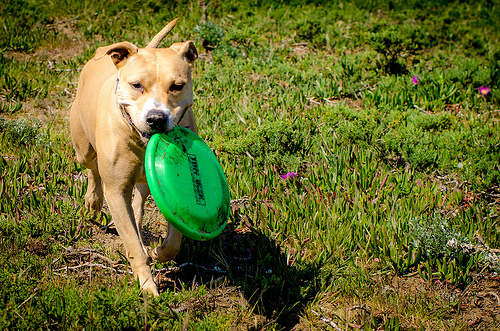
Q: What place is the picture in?
A: It is at the field.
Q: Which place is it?
A: It is a field.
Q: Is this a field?
A: Yes, it is a field.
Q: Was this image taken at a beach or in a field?
A: It was taken at a field.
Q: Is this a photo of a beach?
A: No, the picture is showing a field.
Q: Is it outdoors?
A: Yes, it is outdoors.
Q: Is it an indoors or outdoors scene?
A: It is outdoors.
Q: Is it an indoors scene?
A: No, it is outdoors.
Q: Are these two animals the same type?
A: Yes, all the animals are dogs.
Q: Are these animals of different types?
A: No, all the animals are dogs.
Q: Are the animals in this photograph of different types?
A: No, all the animals are dogs.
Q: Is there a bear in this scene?
A: No, there are no bears.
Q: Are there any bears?
A: No, there are no bears.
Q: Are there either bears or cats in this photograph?
A: No, there are no bears or cats.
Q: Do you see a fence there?
A: No, there are no fences.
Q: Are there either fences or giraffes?
A: No, there are no fences or giraffes.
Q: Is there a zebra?
A: No, there are no zebras.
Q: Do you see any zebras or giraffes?
A: No, there are no zebras or giraffes.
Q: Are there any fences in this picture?
A: No, there are no fences.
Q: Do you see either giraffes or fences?
A: No, there are no fences or giraffes.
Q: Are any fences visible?
A: No, there are no fences.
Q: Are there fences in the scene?
A: No, there are no fences.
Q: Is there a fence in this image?
A: No, there are no fences.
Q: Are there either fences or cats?
A: No, there are no fences or cats.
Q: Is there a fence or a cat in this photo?
A: No, there are no fences or cats.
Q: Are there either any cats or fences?
A: No, there are no fences or cats.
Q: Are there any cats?
A: No, there are no cats.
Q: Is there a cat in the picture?
A: No, there are no cats.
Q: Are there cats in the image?
A: No, there are no cats.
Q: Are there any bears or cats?
A: No, there are no cats or bears.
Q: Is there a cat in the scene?
A: No, there are no cats.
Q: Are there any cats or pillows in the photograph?
A: No, there are no cats or pillows.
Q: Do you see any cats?
A: No, there are no cats.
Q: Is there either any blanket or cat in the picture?
A: No, there are no cats or blankets.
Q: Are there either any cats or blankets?
A: No, there are no cats or blankets.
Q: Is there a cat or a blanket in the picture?
A: No, there are no cats or blankets.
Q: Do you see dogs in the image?
A: Yes, there is a dog.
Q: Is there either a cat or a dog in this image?
A: Yes, there is a dog.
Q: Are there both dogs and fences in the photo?
A: No, there is a dog but no fences.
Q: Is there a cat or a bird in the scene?
A: No, there are no cats or birds.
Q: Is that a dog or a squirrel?
A: That is a dog.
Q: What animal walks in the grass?
A: The dog walks in the grass.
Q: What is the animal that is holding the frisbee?
A: The animal is a dog.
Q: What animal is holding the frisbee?
A: The animal is a dog.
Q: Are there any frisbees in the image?
A: Yes, there is a frisbee.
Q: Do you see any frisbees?
A: Yes, there is a frisbee.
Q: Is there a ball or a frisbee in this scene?
A: Yes, there is a frisbee.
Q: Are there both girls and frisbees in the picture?
A: No, there is a frisbee but no girls.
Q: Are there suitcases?
A: No, there are no suitcases.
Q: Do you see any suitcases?
A: No, there are no suitcases.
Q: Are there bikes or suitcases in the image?
A: No, there are no suitcases or bikes.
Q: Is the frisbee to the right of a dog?
A: Yes, the frisbee is to the right of a dog.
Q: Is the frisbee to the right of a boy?
A: No, the frisbee is to the right of a dog.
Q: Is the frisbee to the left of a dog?
A: No, the frisbee is to the right of a dog.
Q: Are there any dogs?
A: Yes, there is a dog.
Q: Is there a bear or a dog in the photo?
A: Yes, there is a dog.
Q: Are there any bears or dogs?
A: Yes, there is a dog.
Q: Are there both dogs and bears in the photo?
A: No, there is a dog but no bears.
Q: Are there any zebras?
A: No, there are no zebras.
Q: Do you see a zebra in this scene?
A: No, there are no zebras.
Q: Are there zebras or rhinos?
A: No, there are no zebras or rhinos.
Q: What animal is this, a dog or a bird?
A: This is a dog.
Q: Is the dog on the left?
A: Yes, the dog is on the left of the image.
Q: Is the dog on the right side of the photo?
A: No, the dog is on the left of the image.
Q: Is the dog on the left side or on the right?
A: The dog is on the left of the image.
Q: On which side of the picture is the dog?
A: The dog is on the left of the image.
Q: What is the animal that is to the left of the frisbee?
A: The animal is a dog.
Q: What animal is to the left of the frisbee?
A: The animal is a dog.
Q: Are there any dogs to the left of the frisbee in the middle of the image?
A: Yes, there is a dog to the left of the frisbee.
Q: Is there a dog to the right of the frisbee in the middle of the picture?
A: No, the dog is to the left of the frisbee.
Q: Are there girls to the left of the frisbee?
A: No, there is a dog to the left of the frisbee.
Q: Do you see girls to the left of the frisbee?
A: No, there is a dog to the left of the frisbee.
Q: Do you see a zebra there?
A: No, there are no zebras.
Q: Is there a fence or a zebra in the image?
A: No, there are no zebras or fences.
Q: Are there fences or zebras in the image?
A: No, there are no zebras or fences.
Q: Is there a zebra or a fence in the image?
A: No, there are no zebras or fences.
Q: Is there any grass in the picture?
A: Yes, there is grass.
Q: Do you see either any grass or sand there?
A: Yes, there is grass.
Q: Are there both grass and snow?
A: No, there is grass but no snow.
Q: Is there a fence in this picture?
A: No, there are no fences.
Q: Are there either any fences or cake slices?
A: No, there are no fences or cake slices.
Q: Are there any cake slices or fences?
A: No, there are no fences or cake slices.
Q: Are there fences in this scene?
A: No, there are no fences.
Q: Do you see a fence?
A: No, there are no fences.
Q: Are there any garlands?
A: No, there are no garlands.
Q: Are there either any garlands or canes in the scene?
A: No, there are no garlands or canes.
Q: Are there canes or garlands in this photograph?
A: No, there are no garlands or canes.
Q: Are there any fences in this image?
A: No, there are no fences.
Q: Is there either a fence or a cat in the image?
A: No, there are no fences or cats.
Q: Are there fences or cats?
A: No, there are no fences or cats.